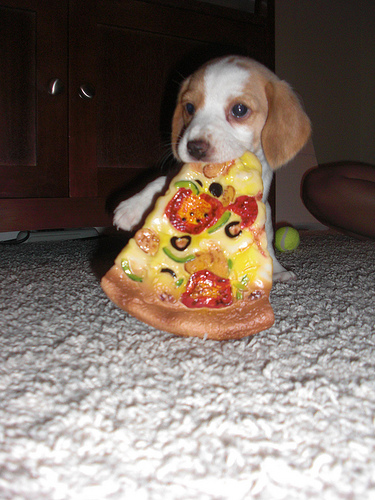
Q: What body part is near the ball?
A: A leg.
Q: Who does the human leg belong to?
A: A person.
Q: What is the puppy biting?
A: A pizza.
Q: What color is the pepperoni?
A: Red.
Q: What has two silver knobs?
A: A cabinet.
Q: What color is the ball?
A: Green.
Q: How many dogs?
A: One.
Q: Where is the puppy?
A: On the floor in a home.